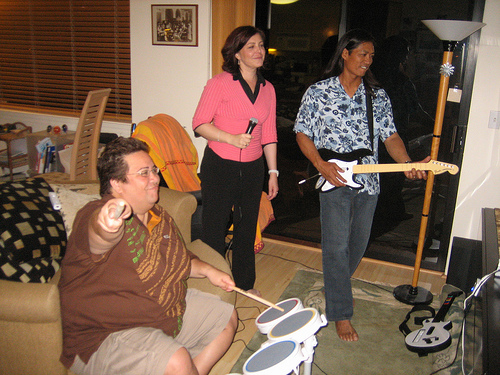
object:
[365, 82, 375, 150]
strap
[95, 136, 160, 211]
head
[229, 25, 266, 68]
head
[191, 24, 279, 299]
woman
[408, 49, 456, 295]
pole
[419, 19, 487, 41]
lamp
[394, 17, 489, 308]
floor lamp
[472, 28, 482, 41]
shade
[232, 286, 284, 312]
drumstick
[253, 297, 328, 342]
drum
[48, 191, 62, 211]
wii remote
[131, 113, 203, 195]
blanket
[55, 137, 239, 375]
person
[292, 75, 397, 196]
shirt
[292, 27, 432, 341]
guitar man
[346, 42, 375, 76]
face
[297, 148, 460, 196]
guitar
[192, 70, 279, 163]
sweater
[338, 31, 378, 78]
head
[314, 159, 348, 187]
hand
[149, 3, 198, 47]
picture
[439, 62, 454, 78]
bow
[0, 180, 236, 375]
chair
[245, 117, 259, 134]
microphone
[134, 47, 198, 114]
wall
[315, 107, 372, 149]
pattern